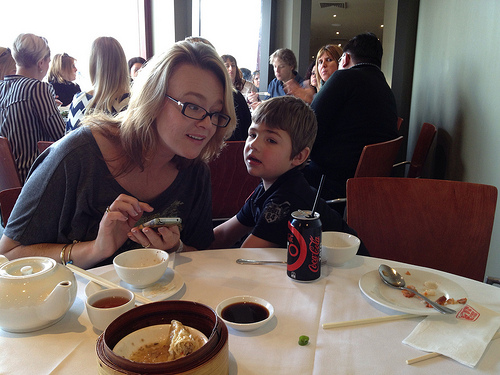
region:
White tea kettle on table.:
[0, 239, 75, 329]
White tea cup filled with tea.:
[80, 289, 137, 326]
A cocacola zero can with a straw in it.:
[286, 174, 327, 281]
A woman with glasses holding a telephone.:
[17, 41, 237, 245]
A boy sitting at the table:
[225, 94, 336, 255]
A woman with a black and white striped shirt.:
[0, 26, 68, 168]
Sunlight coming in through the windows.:
[203, 1, 253, 66]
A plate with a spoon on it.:
[363, 251, 470, 316]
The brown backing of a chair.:
[331, 175, 497, 265]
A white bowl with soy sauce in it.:
[217, 290, 279, 340]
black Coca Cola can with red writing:
[286, 210, 322, 281]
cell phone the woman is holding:
[133, 216, 181, 228]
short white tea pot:
[0, 253, 77, 332]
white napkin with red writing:
[402, 300, 497, 366]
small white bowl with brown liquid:
[216, 294, 275, 331]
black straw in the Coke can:
[310, 173, 325, 215]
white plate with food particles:
[358, 266, 466, 313]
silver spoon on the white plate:
[378, 263, 453, 314]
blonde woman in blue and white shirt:
[63, 37, 130, 135]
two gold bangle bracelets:
[59, 243, 74, 263]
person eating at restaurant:
[316, 28, 396, 189]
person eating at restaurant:
[311, 45, 342, 90]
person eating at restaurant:
[268, 45, 307, 105]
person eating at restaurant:
[63, 37, 132, 127]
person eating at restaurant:
[3, 32, 60, 169]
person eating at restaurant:
[52, 53, 82, 109]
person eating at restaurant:
[126, 55, 142, 87]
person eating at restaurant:
[218, 54, 248, 103]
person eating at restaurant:
[253, 68, 262, 89]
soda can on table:
[283, 208, 322, 283]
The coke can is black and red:
[274, 202, 351, 307]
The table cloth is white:
[203, 265, 276, 311]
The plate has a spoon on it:
[369, 253, 461, 322]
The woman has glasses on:
[159, 90, 238, 155]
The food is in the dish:
[121, 312, 211, 365]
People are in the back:
[265, 23, 392, 140]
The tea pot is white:
[0, 250, 83, 325]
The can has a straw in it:
[291, 157, 353, 282]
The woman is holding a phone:
[106, 185, 208, 260]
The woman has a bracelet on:
[48, 239, 96, 274]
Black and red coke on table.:
[290, 212, 322, 280]